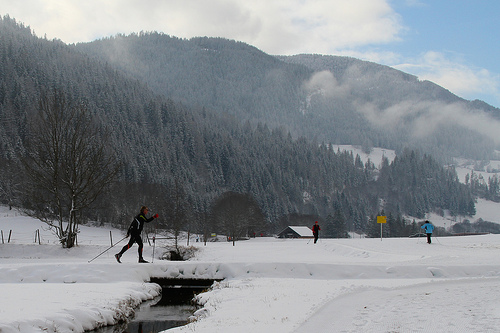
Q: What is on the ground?
A: Snow.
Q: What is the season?
A: Winter.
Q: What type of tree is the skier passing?
A: Deciduous.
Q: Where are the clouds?
A: Sky.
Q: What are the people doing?
A: Skiing.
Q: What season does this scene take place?
A: Winter.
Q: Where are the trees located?
A: Mountains.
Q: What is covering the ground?
A: Snow.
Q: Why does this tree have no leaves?
A: Winter.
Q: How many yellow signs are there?
A: 1.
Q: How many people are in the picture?
A: 3.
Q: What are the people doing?
A: Cross country skiing.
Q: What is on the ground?
A: Snow.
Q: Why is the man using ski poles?
A: To move along.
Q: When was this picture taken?
A: Daytime.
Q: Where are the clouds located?
A: Sky.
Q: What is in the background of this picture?
A: Mountains.